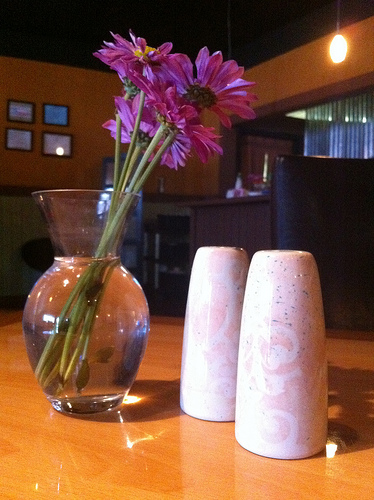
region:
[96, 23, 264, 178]
purple peddled flowers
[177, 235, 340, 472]
salt and pepper shakers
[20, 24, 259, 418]
flowers in water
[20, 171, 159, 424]
a clear vase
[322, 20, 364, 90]
light turned on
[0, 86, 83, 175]
four pictures on an orange wall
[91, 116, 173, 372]
green flower stems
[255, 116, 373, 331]
brown leather back to a seat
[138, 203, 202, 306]
rack to hold dirty dishes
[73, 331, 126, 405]
floating leaves in a vase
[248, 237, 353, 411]
white shaker on table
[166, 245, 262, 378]
white shaker on table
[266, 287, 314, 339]
gray spot on shaker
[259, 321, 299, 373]
white design on shaker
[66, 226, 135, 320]
green stems in vase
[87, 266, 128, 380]
clear water in vase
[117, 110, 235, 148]
pink petals on flower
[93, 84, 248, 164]
pink flowers in vase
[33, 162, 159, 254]
flowers in clear vase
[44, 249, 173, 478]
clear vase on table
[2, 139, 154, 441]
a vase on the table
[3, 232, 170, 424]
water in the vase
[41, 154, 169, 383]
the stems are green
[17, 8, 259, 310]
flowers in the vase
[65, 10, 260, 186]
the flowers are purple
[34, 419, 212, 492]
the table is tan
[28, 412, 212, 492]
the table is made of wood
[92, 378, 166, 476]
light reflecting on the table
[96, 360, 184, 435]
shadow of the vase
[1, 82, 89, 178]
pictures are on the wall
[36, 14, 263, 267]
purple flowers in vase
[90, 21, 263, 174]
purple flowers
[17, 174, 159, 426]
glass flower vase with stems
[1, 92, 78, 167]
four pictures hanging on wall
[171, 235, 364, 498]
salt and pepper on restaurant table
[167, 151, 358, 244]
bar at a restaurant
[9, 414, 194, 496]
reflective surface of restaurant table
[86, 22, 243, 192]
five purple flowers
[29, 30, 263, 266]
five flowers in glass vase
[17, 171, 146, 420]
Vase on the table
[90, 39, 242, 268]
Flowers in the vase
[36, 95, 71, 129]
Frame on the wall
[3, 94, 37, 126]
Frame on the wall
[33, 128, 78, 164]
Frame on the wall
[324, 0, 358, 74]
Light hanging from the ceiling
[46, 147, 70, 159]
Light reflected on frame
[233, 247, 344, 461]
Shaker on the table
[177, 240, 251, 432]
Shaker on the table